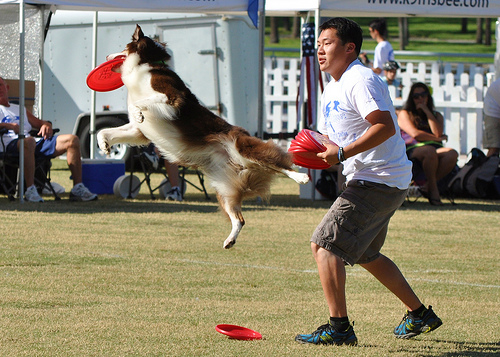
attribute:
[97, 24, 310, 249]
dog — jumping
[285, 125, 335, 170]
frisbees — red, stacked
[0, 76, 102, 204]
man — sitting, watching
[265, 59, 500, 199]
fences — white, wooden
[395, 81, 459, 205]
woman — sitting, seated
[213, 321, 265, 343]
frisbee — red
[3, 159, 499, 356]
ground — green, brown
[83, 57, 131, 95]
frisbee — re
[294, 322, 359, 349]
shoes — blue, athletic, green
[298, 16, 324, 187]
flag — american, united states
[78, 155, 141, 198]
cooler — blue, white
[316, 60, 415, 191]
tshirt — white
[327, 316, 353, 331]
socks — dark